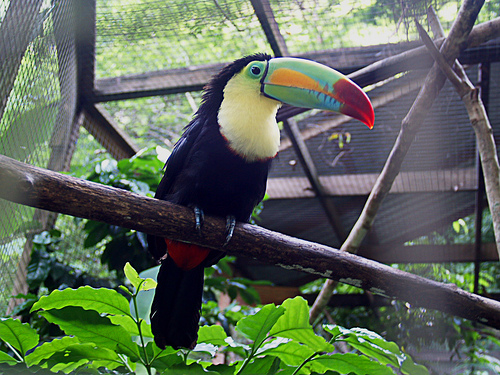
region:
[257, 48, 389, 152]
beak of the bird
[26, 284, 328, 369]
leaves on the tree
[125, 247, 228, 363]
tail feathers of the bird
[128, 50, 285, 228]
black and white body of bird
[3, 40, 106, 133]
cage behind the bird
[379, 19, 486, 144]
branches above the bird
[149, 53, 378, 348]
Toucan sitting on a branch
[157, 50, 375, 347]
Bird with black feathers and yellow throat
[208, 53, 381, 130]
Bird with a green beak and red tip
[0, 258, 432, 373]
Plant leaves under a bird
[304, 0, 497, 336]
Branches that cross at the top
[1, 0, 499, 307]
Wire fencing with a wood frame behind a bird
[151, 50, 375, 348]
Bird with green rimmed eyes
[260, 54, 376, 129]
Beak with a red tip and orange spot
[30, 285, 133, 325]
Plant leaf attached to a stem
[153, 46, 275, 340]
long black feathers on parrot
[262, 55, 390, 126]
turquoise and red and yellow beak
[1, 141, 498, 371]
green leaves below and behind parrot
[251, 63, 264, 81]
bird has turquoise lined eye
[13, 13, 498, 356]
plants and wooden supports in sanctuary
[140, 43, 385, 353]
parrot sitting with beak closed and not talking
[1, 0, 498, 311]
trees visible from outside the metal cage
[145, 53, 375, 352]
A mostly black toucan with colorful beak.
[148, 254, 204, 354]
Black feathers on a toucans rear.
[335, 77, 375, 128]
Red tips of a bird beak.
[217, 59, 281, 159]
White feathers on a birds neck.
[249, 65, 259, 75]
Round black bird eye.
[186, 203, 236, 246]
Two black bird claws.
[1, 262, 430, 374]
Green leaves under a toucan.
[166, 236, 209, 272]
Red feathers under a bird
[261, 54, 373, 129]
A blue, green, yellow and red bird beak.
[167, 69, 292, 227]
a parrot on a stick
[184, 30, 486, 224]
a bird with a colorful beak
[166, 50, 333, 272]
a bird sitting in a cage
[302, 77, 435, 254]
roof to a bird cage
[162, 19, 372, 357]
a bird that is black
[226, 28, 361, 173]
a beak that is red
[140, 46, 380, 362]
black and yellow toucan bird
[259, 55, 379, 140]
multi-colored beak of toucan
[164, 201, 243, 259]
feet of toucan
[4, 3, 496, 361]
toucan perched on tree branch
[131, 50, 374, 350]
the bird is perched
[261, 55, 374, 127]
the beak is colorful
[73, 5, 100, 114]
metal beam upper cage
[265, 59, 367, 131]
the toucan beak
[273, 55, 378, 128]
the toucan beak red yellow and green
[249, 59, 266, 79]
little eye left of the toucan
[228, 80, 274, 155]
white plumage of the toucan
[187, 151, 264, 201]
black plumage of the toucan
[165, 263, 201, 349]
black tail plumage of the toucan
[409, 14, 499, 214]
brown large stick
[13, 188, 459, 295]
Vertical long wooden rod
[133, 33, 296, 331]
toucan standing on vertical long wooden rod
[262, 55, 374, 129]
bird beak is colorful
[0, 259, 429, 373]
leaves beneath perched bird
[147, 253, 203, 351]
blalck tail on bird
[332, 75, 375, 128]
tip of beak is red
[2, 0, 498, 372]
bird inside wire enclosure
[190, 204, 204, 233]
black claw on bird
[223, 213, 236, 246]
black claw on bird